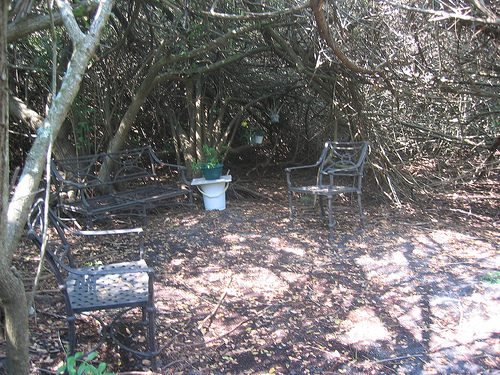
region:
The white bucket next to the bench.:
[195, 175, 225, 212]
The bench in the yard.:
[53, 144, 198, 234]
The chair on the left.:
[25, 190, 168, 355]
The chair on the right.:
[290, 137, 367, 219]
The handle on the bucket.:
[193, 185, 235, 197]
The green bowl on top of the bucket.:
[200, 163, 220, 178]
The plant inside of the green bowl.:
[201, 146, 224, 170]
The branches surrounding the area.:
[18, 1, 488, 192]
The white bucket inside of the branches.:
[247, 130, 263, 144]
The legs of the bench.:
[51, 193, 196, 235]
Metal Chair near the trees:
[276, 125, 368, 223]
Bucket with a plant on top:
[183, 150, 243, 222]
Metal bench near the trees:
[46, 155, 216, 247]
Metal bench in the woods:
[30, 200, 216, 342]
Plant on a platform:
[196, 145, 226, 184]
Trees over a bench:
[142, 36, 270, 141]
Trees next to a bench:
[343, 48, 460, 188]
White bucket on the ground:
[173, 148, 251, 239]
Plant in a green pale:
[198, 148, 225, 175]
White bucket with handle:
[192, 181, 248, 215]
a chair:
[61, 211, 156, 325]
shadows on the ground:
[319, 262, 441, 359]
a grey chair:
[274, 140, 376, 226]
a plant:
[192, 148, 224, 172]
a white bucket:
[197, 182, 234, 208]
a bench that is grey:
[51, 158, 196, 214]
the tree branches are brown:
[391, 15, 486, 193]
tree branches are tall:
[160, 21, 261, 74]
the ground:
[410, 252, 490, 354]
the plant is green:
[191, 146, 223, 165]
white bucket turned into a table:
[194, 178, 231, 211]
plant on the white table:
[193, 145, 223, 180]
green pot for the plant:
[200, 163, 222, 179]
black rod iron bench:
[48, 145, 194, 237]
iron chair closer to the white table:
[287, 136, 363, 223]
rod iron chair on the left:
[27, 204, 158, 369]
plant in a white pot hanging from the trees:
[249, 121, 264, 147]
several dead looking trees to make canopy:
[15, 9, 498, 188]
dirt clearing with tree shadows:
[138, 220, 498, 373]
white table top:
[192, 177, 231, 184]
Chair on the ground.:
[281, 135, 373, 231]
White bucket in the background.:
[194, 178, 234, 210]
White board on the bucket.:
[188, 174, 231, 188]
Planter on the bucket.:
[188, 141, 226, 182]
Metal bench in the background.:
[46, 145, 203, 225]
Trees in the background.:
[0, 0, 494, 188]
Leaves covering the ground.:
[5, 174, 499, 372]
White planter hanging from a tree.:
[250, 131, 262, 146]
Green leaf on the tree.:
[34, 122, 51, 141]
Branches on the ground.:
[186, 274, 279, 349]